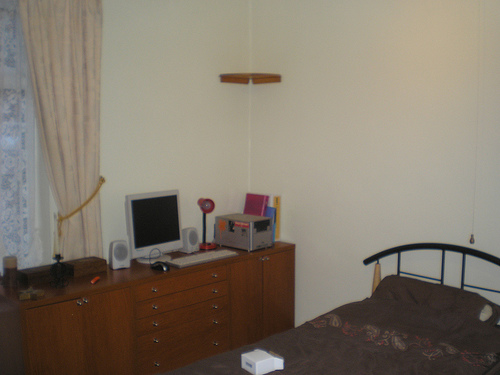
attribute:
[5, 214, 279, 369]
dresser — brown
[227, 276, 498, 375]
bedspread — brown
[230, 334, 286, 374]
box — white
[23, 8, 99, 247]
curtains — white, hanging, lace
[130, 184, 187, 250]
monitor — off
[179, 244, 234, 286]
keyboard — white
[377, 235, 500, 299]
headboard — black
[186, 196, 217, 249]
light — red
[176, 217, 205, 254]
speaker — rectangular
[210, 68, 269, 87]
shelf — brown